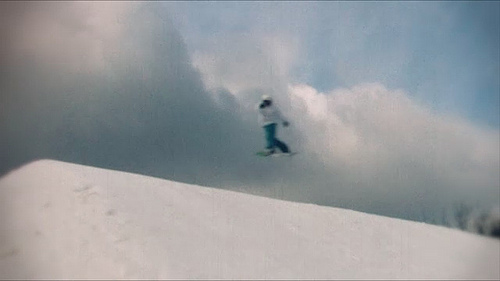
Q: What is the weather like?
A: It is cloudy.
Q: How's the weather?
A: It is cloudy.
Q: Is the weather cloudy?
A: Yes, it is cloudy.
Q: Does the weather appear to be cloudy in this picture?
A: Yes, it is cloudy.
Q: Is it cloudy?
A: Yes, it is cloudy.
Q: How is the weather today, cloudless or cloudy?
A: It is cloudy.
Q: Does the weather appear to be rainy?
A: No, it is cloudy.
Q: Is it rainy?
A: No, it is cloudy.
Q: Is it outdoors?
A: Yes, it is outdoors.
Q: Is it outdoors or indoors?
A: It is outdoors.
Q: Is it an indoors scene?
A: No, it is outdoors.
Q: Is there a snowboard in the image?
A: Yes, there is a snowboard.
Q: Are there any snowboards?
A: Yes, there is a snowboard.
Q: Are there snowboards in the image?
A: Yes, there is a snowboard.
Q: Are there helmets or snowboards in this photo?
A: Yes, there is a snowboard.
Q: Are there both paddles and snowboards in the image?
A: No, there is a snowboard but no paddles.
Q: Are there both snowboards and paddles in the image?
A: No, there is a snowboard but no paddles.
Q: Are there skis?
A: No, there are no skis.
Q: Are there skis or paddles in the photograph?
A: No, there are no skis or paddles.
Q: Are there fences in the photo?
A: No, there are no fences.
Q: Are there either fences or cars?
A: No, there are no fences or cars.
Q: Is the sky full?
A: Yes, the sky is full.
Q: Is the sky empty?
A: No, the sky is full.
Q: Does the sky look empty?
A: No, the sky is full.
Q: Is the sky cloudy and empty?
A: No, the sky is cloudy but full.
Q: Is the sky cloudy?
A: Yes, the sky is cloudy.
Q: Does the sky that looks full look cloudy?
A: Yes, the sky is cloudy.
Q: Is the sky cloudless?
A: No, the sky is cloudy.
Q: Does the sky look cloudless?
A: No, the sky is cloudy.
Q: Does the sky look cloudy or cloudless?
A: The sky is cloudy.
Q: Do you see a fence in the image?
A: No, there are no fences.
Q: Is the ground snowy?
A: Yes, the ground is snowy.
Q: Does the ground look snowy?
A: Yes, the ground is snowy.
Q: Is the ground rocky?
A: No, the ground is snowy.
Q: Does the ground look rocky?
A: No, the ground is snowy.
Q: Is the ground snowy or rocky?
A: The ground is snowy.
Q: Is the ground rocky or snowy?
A: The ground is snowy.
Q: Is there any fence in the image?
A: No, there are no fences.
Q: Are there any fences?
A: No, there are no fences.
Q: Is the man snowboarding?
A: Yes, the man is snowboarding.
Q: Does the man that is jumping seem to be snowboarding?
A: Yes, the man is snowboarding.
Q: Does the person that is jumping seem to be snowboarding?
A: Yes, the man is snowboarding.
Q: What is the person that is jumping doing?
A: The man is snowboarding.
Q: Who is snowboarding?
A: The man is snowboarding.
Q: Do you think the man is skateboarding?
A: No, the man is snowboarding.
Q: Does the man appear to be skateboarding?
A: No, the man is snowboarding.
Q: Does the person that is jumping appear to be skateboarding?
A: No, the man is snowboarding.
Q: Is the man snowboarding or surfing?
A: The man is snowboarding.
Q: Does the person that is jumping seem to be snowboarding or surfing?
A: The man is snowboarding.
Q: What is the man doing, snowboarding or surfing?
A: The man is snowboarding.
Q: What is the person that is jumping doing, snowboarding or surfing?
A: The man is snowboarding.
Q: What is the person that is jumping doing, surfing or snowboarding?
A: The man is snowboarding.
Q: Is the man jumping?
A: Yes, the man is jumping.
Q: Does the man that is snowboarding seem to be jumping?
A: Yes, the man is jumping.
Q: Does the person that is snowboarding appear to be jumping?
A: Yes, the man is jumping.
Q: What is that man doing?
A: The man is jumping.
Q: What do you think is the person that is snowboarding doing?
A: The man is jumping.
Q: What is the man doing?
A: The man is jumping.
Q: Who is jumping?
A: The man is jumping.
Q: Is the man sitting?
A: No, the man is jumping.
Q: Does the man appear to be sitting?
A: No, the man is jumping.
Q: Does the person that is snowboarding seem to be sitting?
A: No, the man is jumping.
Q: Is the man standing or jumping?
A: The man is jumping.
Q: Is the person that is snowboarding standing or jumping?
A: The man is jumping.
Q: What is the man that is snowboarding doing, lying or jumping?
A: The man is jumping.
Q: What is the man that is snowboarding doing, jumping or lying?
A: The man is jumping.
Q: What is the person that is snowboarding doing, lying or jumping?
A: The man is jumping.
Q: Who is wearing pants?
A: The man is wearing pants.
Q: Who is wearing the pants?
A: The man is wearing pants.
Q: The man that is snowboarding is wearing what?
A: The man is wearing pants.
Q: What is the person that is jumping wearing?
A: The man is wearing pants.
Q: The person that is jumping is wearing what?
A: The man is wearing pants.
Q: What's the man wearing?
A: The man is wearing pants.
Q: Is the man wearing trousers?
A: Yes, the man is wearing trousers.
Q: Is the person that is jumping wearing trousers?
A: Yes, the man is wearing trousers.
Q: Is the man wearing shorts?
A: No, the man is wearing trousers.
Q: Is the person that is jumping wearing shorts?
A: No, the man is wearing trousers.